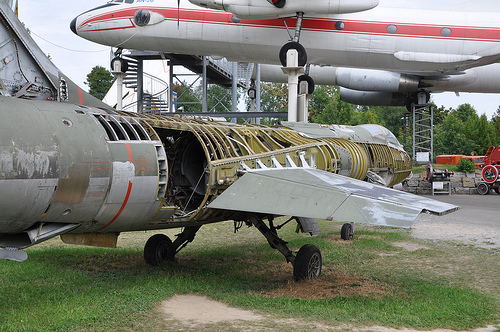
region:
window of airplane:
[426, 6, 463, 63]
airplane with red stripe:
[46, 1, 498, 103]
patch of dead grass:
[271, 283, 398, 323]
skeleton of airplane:
[206, 106, 365, 191]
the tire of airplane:
[278, 245, 365, 280]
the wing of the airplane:
[223, 146, 470, 261]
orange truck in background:
[436, 141, 490, 168]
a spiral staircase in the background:
[118, 74, 173, 119]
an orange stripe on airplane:
[113, 143, 143, 263]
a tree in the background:
[448, 111, 495, 158]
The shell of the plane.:
[223, 135, 282, 165]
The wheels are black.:
[268, 249, 333, 282]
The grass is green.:
[407, 293, 472, 321]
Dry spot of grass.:
[293, 268, 335, 299]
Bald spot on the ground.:
[170, 302, 212, 321]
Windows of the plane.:
[363, 10, 422, 41]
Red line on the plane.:
[168, 0, 214, 26]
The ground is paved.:
[466, 200, 494, 233]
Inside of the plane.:
[150, 143, 199, 178]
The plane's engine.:
[332, 61, 429, 102]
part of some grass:
[389, 287, 447, 320]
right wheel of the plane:
[292, 250, 327, 275]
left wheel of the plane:
[145, 240, 175, 276]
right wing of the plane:
[295, 177, 420, 217]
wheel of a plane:
[272, 27, 302, 59]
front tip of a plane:
[66, 9, 93, 46]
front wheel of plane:
[343, 220, 359, 240]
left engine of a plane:
[335, 62, 420, 94]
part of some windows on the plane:
[321, 8, 398, 38]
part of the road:
[466, 192, 488, 229]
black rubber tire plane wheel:
[288, 240, 326, 287]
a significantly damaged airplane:
[1, 43, 471, 298]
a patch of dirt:
[173, 298, 207, 316]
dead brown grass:
[291, 273, 378, 300]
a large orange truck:
[434, 148, 491, 175]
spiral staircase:
[103, 45, 176, 125]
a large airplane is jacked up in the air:
[58, 1, 498, 114]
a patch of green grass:
[1, 273, 130, 330]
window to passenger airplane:
[382, 21, 402, 37]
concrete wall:
[451, 180, 463, 193]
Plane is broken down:
[34, 80, 482, 271]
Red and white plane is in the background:
[66, 4, 498, 123]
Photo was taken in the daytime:
[10, 9, 487, 329]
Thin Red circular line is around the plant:
[84, 133, 149, 245]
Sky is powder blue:
[31, 5, 136, 80]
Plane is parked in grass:
[41, 231, 378, 330]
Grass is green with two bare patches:
[133, 247, 416, 330]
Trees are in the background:
[319, 88, 499, 171]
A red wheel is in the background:
[474, 161, 499, 188]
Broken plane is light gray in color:
[8, 105, 467, 270]